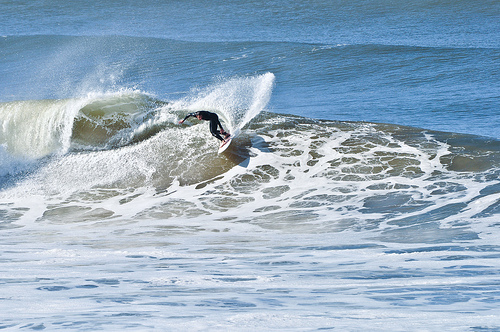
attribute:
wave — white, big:
[6, 92, 93, 177]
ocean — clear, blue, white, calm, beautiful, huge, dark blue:
[7, 14, 486, 325]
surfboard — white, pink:
[217, 135, 238, 157]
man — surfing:
[185, 110, 229, 146]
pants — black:
[210, 119, 225, 143]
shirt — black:
[192, 110, 211, 123]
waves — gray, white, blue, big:
[7, 85, 283, 184]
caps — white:
[35, 149, 280, 180]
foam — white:
[255, 143, 447, 259]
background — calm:
[10, 16, 496, 150]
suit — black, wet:
[199, 112, 225, 141]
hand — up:
[174, 111, 199, 132]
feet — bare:
[218, 132, 230, 145]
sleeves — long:
[186, 111, 198, 123]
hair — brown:
[194, 111, 204, 117]